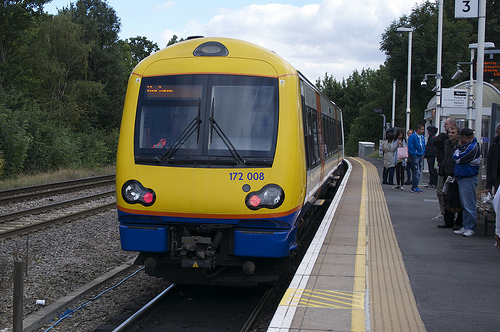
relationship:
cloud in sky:
[278, 10, 392, 70] [140, 7, 395, 79]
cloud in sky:
[120, 0, 423, 88] [40, 3, 431, 84]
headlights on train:
[119, 177, 284, 211] [114, 34, 344, 289]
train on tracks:
[114, 34, 344, 289] [108, 282, 274, 331]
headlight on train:
[237, 178, 287, 216] [107, 32, 351, 300]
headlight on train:
[118, 176, 158, 209] [107, 32, 351, 300]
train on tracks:
[114, 34, 344, 289] [108, 276, 274, 327]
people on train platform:
[451, 126, 483, 238] [265, 151, 499, 328]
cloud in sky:
[120, 0, 423, 88] [189, 1, 388, 45]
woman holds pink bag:
[393, 128, 411, 188] [395, 145, 412, 162]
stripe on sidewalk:
[345, 152, 377, 327] [340, 154, 487, 327]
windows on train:
[144, 75, 279, 166] [99, 23, 355, 265]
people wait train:
[336, 80, 488, 282] [108, 39, 404, 276]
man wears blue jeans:
[403, 119, 425, 191] [408, 153, 423, 188]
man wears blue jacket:
[403, 119, 425, 191] [405, 129, 428, 157]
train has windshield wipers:
[99, 23, 355, 265] [150, 117, 295, 182]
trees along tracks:
[13, 17, 108, 149] [1, 175, 110, 232]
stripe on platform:
[345, 155, 368, 331] [269, 155, 500, 332]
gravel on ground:
[8, 215, 115, 301] [2, 185, 130, 312]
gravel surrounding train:
[8, 215, 115, 301] [87, 40, 367, 268]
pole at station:
[394, 17, 419, 143] [264, 84, 499, 319]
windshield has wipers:
[145, 85, 271, 160] [163, 119, 240, 167]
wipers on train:
[163, 119, 240, 167] [120, 39, 345, 264]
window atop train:
[134, 82, 200, 102] [114, 34, 344, 289]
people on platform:
[451, 126, 483, 238] [312, 155, 455, 330]